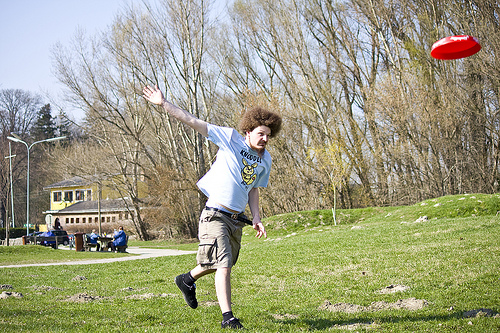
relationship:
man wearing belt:
[178, 92, 298, 203] [204, 205, 274, 241]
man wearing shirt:
[178, 92, 298, 203] [192, 122, 266, 210]